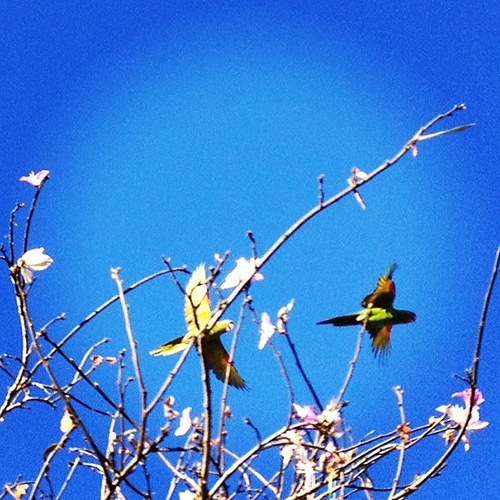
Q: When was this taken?
A: Daytime.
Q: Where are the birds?
A: In the sky.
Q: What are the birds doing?
A: Flying.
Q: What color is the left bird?
A: Yellow.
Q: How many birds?
A: 2.